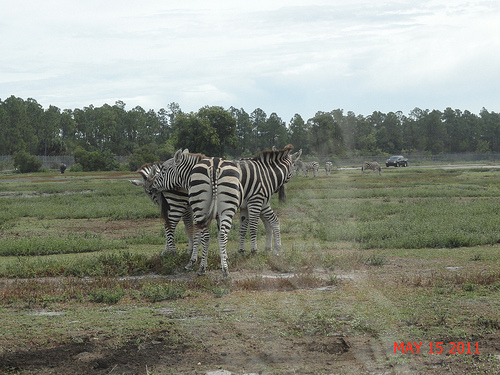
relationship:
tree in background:
[177, 110, 219, 162] [2, 3, 498, 193]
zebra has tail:
[228, 143, 308, 259] [197, 159, 219, 227]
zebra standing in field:
[149, 145, 242, 279] [2, 158, 484, 373]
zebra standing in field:
[228, 143, 308, 259] [2, 158, 484, 373]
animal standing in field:
[324, 161, 334, 175] [2, 158, 484, 373]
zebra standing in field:
[358, 158, 385, 178] [2, 158, 484, 373]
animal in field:
[324, 161, 338, 172] [306, 124, 484, 241]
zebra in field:
[150, 146, 243, 284] [13, 100, 473, 281]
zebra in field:
[238, 147, 318, 247] [18, 92, 484, 242]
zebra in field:
[150, 146, 243, 284] [0, 78, 238, 248]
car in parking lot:
[376, 142, 415, 170] [376, 135, 446, 172]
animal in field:
[324, 161, 334, 175] [66, 100, 464, 223]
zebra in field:
[358, 153, 388, 174] [22, 61, 474, 304]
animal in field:
[324, 161, 334, 175] [24, 73, 484, 232]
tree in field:
[177, 110, 212, 152] [50, 96, 480, 256]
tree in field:
[177, 110, 219, 162] [52, 82, 450, 345]